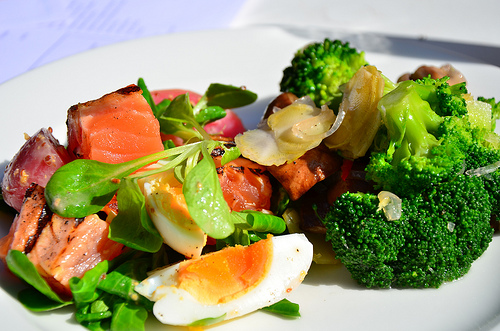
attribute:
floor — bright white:
[30, 15, 126, 30]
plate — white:
[159, 24, 299, 96]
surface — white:
[87, 10, 157, 35]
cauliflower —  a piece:
[310, 72, 499, 291]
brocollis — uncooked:
[277, 33, 499, 291]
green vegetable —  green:
[321, 76, 496, 286]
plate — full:
[2, 26, 499, 328]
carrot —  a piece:
[61, 86, 181, 161]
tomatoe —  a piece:
[213, 157, 269, 212]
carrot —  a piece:
[13, 188, 114, 296]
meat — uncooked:
[71, 86, 159, 165]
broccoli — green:
[320, 175, 495, 292]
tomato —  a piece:
[202, 112, 242, 139]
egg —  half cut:
[134, 228, 314, 324]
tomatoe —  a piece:
[4, 129, 76, 219]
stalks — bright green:
[375, 81, 442, 163]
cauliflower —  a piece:
[277, 35, 368, 105]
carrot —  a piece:
[33, 215, 68, 268]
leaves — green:
[111, 181, 156, 254]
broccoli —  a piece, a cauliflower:
[378, 84, 460, 184]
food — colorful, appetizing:
[0, 27, 499, 328]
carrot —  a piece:
[14, 202, 52, 244]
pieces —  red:
[3, 127, 64, 209]